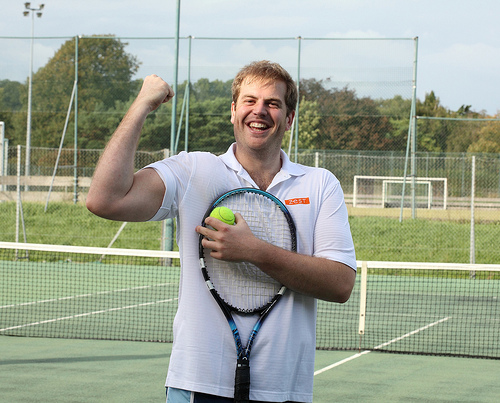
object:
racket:
[185, 171, 310, 401]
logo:
[285, 197, 311, 206]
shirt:
[148, 146, 359, 401]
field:
[83, 96, 475, 371]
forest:
[327, 93, 489, 155]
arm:
[86, 100, 190, 222]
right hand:
[143, 73, 175, 103]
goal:
[353, 175, 448, 210]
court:
[0, 264, 497, 402]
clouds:
[137, 42, 208, 71]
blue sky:
[0, 0, 498, 118]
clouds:
[323, 21, 387, 62]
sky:
[4, 2, 496, 86]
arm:
[256, 178, 358, 304]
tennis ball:
[207, 201, 239, 227]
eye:
[244, 98, 256, 104]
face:
[233, 78, 287, 150]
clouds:
[24, 42, 54, 60]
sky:
[425, 7, 486, 89]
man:
[183, 35, 360, 387]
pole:
[24, 1, 36, 191]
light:
[38, 2, 48, 10]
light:
[36, 12, 42, 18]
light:
[24, 2, 30, 9]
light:
[22, 11, 29, 17]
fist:
[135, 69, 175, 110]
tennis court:
[16, 242, 498, 399]